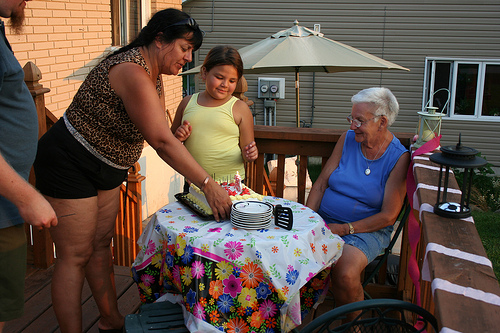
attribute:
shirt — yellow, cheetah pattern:
[181, 92, 244, 185]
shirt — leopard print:
[68, 49, 160, 170]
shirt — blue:
[322, 130, 411, 235]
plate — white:
[235, 196, 273, 228]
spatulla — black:
[266, 203, 295, 231]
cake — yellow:
[188, 180, 263, 215]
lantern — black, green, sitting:
[430, 135, 486, 221]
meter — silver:
[256, 78, 285, 109]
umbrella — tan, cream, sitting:
[177, 20, 410, 76]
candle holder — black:
[431, 134, 487, 219]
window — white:
[424, 56, 499, 121]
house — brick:
[2, 2, 184, 129]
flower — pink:
[228, 243, 243, 260]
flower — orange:
[241, 260, 264, 287]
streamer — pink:
[408, 135, 443, 331]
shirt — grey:
[0, 22, 37, 229]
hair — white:
[351, 88, 398, 125]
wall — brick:
[0, 0, 182, 144]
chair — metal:
[287, 296, 441, 333]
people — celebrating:
[1, 1, 409, 331]